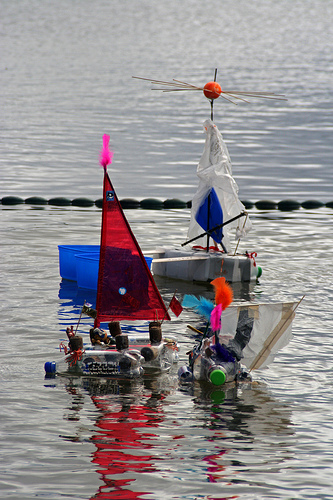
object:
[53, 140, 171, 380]
boat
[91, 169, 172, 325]
sail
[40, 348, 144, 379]
bottle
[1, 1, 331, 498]
water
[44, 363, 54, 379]
cap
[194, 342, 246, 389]
bottle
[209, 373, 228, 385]
cap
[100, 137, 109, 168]
feather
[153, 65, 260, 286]
boat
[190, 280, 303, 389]
boat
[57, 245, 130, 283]
tub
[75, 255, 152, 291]
tub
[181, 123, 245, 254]
sail